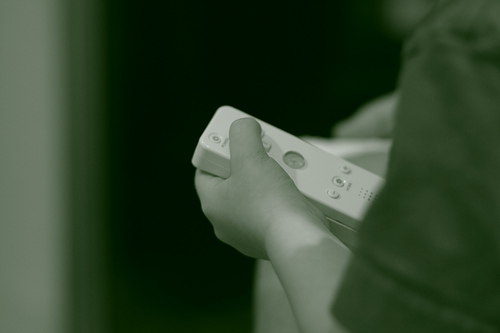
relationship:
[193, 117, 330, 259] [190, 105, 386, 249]
hand holds a controller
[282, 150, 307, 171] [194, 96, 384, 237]
button on a controller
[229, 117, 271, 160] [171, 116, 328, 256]
button thumb on a hand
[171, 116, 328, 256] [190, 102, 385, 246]
hand on a controller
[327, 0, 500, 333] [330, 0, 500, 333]
shirt on a person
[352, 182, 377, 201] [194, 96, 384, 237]
holes in a controller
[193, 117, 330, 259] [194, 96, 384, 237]
hand holding controller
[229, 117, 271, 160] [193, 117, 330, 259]
button thumb on a hand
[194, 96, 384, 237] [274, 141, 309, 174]
controller on a button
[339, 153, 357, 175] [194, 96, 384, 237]
button on a controller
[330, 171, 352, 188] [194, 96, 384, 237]
button on a controller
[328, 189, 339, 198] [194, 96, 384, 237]
button on a controller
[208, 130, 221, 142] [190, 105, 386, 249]
button on a controller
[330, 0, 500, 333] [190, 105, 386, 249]
person holds a controller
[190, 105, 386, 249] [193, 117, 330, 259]
controller held in a hand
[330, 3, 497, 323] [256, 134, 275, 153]
person presses a button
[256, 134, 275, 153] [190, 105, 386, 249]
button on a controller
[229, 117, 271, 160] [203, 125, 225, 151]
button thumb on a button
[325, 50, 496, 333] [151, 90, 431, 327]
shirt on a person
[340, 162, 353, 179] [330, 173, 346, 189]
button by a button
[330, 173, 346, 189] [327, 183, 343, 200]
button by a button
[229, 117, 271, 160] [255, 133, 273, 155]
button thumb by a button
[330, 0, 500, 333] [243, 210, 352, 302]
person has arm